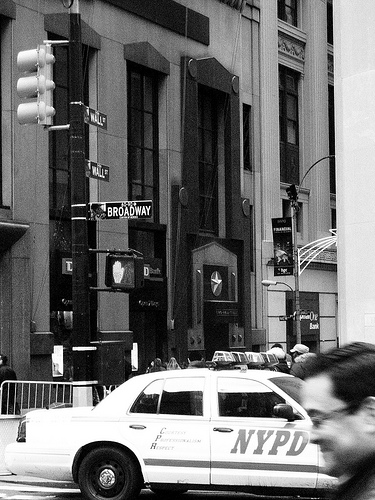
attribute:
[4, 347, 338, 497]
police car — white, police's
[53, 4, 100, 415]
pole — tall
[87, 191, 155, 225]
street sign — black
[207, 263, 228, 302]
star — large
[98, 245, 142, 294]
light — electronic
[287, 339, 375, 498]
man — moving, walking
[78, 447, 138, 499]
tire — round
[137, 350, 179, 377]
people — walking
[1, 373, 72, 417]
fence — metal, silver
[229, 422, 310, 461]
nypd —  NYPD's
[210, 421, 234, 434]
door opener — black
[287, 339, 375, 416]
hair — black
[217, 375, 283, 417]
glass — shiny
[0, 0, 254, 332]
cement bricks — large